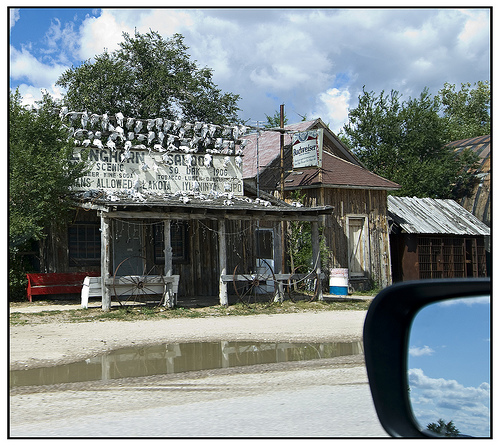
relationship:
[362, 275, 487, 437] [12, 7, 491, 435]
mirror on photo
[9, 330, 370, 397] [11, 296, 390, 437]
puddle on road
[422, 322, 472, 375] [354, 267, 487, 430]
sky in mirror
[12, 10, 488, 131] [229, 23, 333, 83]
clouds in blue sky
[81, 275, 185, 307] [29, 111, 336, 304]
bench next to building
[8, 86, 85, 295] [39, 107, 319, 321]
tree within building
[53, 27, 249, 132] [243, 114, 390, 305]
tree within building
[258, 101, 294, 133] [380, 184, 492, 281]
tree within building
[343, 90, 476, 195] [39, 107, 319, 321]
tree within building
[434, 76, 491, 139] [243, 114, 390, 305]
tree within building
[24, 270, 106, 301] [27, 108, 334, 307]
bench in front of store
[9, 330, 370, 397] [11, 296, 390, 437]
puddle in road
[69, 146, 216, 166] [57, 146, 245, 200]
longhorn saloon on sign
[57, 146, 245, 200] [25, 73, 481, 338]
sign on building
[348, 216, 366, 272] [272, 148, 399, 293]
doorway on shack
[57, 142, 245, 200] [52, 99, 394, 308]
sign on store